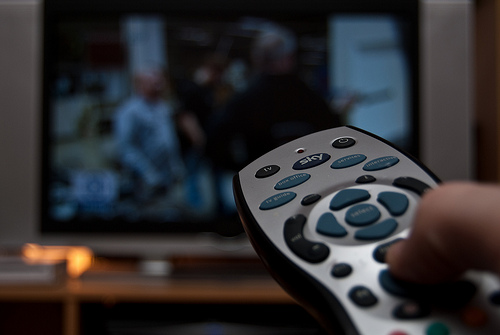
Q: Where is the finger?
A: On the remote control.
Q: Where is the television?
A: In front of the remote.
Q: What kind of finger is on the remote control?
A: A thumb.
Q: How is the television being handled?
A: With a remote control.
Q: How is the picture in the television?
A: Blurry.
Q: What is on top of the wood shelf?
A: A television.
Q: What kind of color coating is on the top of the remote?
A: Silver.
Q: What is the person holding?
A: A remote control.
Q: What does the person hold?
A: A remote.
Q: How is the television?
A: On.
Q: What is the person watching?
A: TV.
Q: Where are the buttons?
A: On the remote.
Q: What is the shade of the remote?
A: Silver.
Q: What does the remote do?
A: Controls the TV.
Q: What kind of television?
A: Flat screen.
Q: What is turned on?
A: The flat screen TV.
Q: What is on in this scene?
A: Television set.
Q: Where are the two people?
A: On television set.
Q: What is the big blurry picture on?
A: A tv.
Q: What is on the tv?
A: There are some people.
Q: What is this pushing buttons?
A: A finger.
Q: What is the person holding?
A: A remote.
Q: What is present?
A: A remote.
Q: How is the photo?
A: Blurry.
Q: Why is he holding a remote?
A: To change the channel.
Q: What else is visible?
A: A television.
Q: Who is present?
A: A man.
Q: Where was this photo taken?
A: In a house.